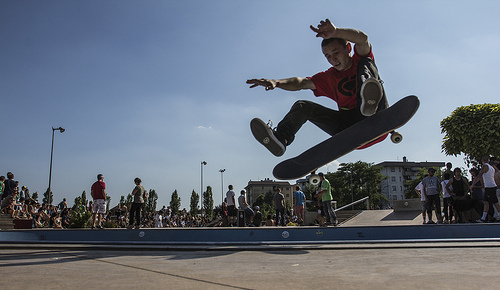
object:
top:
[481, 163, 498, 188]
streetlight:
[49, 126, 64, 221]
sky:
[0, 0, 499, 213]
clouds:
[399, 6, 482, 80]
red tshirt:
[306, 42, 388, 151]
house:
[370, 155, 448, 209]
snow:
[84, 37, 196, 129]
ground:
[0, 233, 499, 289]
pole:
[46, 127, 54, 220]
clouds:
[172, 97, 208, 124]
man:
[243, 17, 399, 157]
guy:
[246, 15, 391, 156]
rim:
[0, 222, 499, 241]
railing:
[328, 195, 370, 225]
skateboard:
[272, 94, 419, 182]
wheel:
[389, 129, 402, 144]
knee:
[130, 211, 134, 215]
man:
[90, 174, 108, 228]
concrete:
[0, 237, 499, 290]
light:
[60, 127, 66, 133]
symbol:
[337, 76, 357, 97]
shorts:
[91, 199, 107, 214]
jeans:
[276, 100, 386, 152]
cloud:
[38, 19, 140, 88]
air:
[114, 11, 453, 191]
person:
[225, 185, 239, 228]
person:
[238, 190, 256, 226]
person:
[273, 187, 287, 227]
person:
[293, 185, 307, 223]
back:
[226, 189, 234, 206]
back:
[273, 192, 283, 208]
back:
[294, 190, 307, 208]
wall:
[393, 202, 408, 212]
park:
[0, 0, 499, 290]